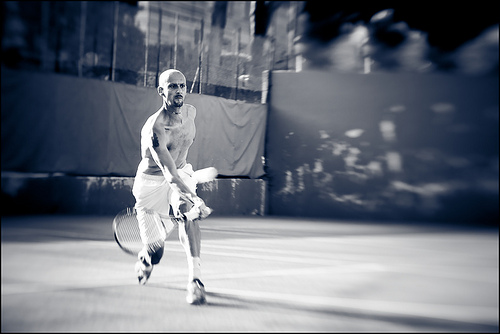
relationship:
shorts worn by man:
[126, 171, 208, 238] [137, 68, 214, 306]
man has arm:
[137, 68, 214, 306] [143, 121, 205, 211]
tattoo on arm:
[143, 128, 167, 151] [143, 121, 205, 211]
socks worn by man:
[179, 254, 205, 279] [137, 68, 214, 306]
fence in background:
[2, 1, 273, 102] [6, 71, 269, 119]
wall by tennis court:
[258, 70, 493, 225] [0, 214, 498, 333]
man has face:
[131, 69, 212, 306] [163, 71, 188, 108]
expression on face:
[171, 74, 188, 107] [163, 71, 188, 108]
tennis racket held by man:
[105, 202, 200, 262] [131, 69, 212, 306]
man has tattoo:
[131, 69, 212, 306] [143, 128, 167, 151]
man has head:
[131, 69, 212, 306] [153, 67, 191, 108]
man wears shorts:
[131, 69, 212, 306] [126, 171, 208, 238]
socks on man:
[179, 254, 205, 279] [131, 69, 212, 306]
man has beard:
[131, 69, 212, 306] [171, 94, 186, 106]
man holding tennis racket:
[137, 68, 214, 306] [105, 202, 200, 262]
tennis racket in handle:
[105, 202, 200, 262] [190, 207, 212, 221]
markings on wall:
[320, 124, 438, 200] [258, 70, 493, 225]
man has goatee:
[137, 68, 214, 306] [171, 94, 186, 106]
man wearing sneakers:
[137, 68, 214, 306] [133, 258, 207, 313]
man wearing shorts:
[137, 68, 214, 306] [126, 171, 208, 238]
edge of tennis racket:
[108, 221, 133, 257] [112, 208, 214, 255]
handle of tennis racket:
[181, 208, 205, 222] [112, 208, 214, 255]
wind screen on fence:
[1, 66, 265, 180] [2, 1, 273, 102]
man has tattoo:
[137, 68, 214, 306] [143, 128, 167, 151]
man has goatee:
[137, 68, 214, 306] [170, 99, 188, 109]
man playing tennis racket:
[137, 68, 214, 306] [112, 208, 214, 255]